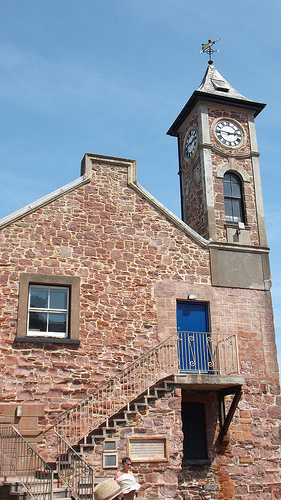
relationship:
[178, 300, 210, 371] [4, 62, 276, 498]
door on building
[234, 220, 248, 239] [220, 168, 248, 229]
camera on window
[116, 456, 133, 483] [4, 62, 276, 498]
woman standing by building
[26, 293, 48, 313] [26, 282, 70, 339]
reflection in window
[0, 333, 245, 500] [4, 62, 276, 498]
staircase leading to upper level of building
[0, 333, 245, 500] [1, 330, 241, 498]
staircase with railing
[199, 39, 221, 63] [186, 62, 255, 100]
cross on top of roof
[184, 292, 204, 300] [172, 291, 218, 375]
light of door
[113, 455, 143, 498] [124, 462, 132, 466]
woman wearing sunglasses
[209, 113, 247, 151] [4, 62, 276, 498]
clock on building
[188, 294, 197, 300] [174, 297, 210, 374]
lamp on door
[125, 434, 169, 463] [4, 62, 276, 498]
sign on building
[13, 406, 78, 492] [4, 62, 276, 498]
staircase to building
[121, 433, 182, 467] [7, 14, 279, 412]
plaque on building.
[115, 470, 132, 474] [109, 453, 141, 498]
shirt on woman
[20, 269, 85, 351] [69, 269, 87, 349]
window in framing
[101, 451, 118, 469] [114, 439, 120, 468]
chalkboard in framing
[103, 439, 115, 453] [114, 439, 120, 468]
chalkboard in framing